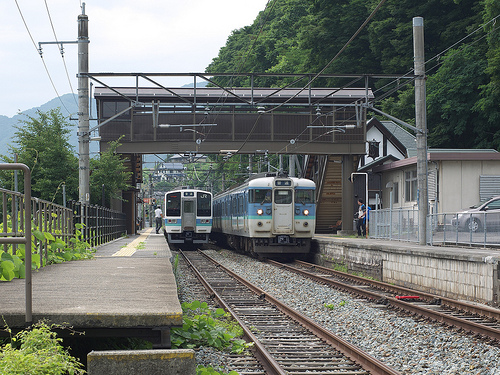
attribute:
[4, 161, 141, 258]
fence — old, metal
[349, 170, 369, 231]
post — curved, white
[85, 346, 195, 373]
cement — faded, yellow, painted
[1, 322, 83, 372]
plant — light green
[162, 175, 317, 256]
train cars — blue and white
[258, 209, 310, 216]
headlights — on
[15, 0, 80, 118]
wires — telephone wires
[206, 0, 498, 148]
foliage — lush, green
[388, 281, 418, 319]
item — red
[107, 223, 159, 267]
stripe — white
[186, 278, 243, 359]
shrub — green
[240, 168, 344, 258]
train — blue and white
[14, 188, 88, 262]
rails — silver and gray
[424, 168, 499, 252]
car — silver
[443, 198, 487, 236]
sedan — small gold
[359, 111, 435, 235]
building — white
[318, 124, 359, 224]
stairway — old metal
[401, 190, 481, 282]
fence — small